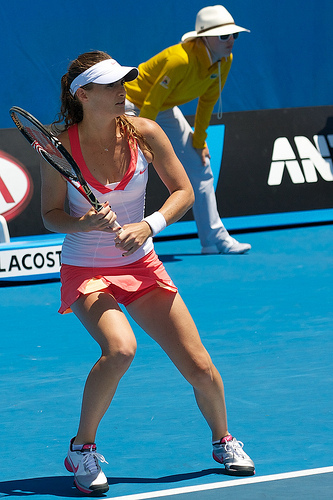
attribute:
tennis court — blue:
[186, 250, 329, 384]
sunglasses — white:
[216, 32, 242, 41]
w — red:
[32, 127, 58, 156]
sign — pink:
[66, 455, 81, 471]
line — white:
[256, 461, 332, 483]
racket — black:
[11, 102, 96, 210]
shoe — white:
[209, 434, 260, 475]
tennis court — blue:
[185, 245, 330, 350]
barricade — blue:
[252, 12, 330, 100]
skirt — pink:
[57, 252, 178, 317]